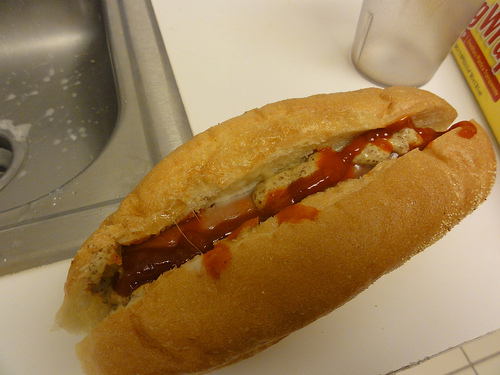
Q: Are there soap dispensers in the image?
A: No, there are no soap dispensers.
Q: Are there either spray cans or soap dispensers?
A: No, there are no soap dispensers or spray cans.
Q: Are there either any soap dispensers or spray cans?
A: No, there are no soap dispensers or spray cans.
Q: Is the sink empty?
A: Yes, the sink is empty.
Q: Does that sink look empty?
A: Yes, the sink is empty.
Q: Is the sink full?
A: No, the sink is empty.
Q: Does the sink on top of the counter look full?
A: No, the sink is empty.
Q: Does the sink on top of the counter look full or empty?
A: The sink is empty.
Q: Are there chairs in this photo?
A: No, there are no chairs.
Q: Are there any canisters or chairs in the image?
A: No, there are no chairs or canisters.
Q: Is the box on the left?
A: No, the box is on the right of the image.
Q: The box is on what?
A: The box is on the counter.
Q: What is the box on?
A: The box is on the counter.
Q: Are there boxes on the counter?
A: Yes, there is a box on the counter.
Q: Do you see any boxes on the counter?
A: Yes, there is a box on the counter.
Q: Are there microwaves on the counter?
A: No, there is a box on the counter.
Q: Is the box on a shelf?
A: No, the box is on a counter.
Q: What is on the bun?
A: The seeds are on the bun.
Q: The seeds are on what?
A: The seeds are on the bun.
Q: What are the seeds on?
A: The seeds are on the bun.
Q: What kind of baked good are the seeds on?
A: The seeds are on the bun.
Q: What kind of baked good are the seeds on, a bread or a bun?
A: The seeds are on a bun.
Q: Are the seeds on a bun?
A: Yes, the seeds are on a bun.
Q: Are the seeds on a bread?
A: No, the seeds are on a bun.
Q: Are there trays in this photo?
A: No, there are no trays.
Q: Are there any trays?
A: No, there are no trays.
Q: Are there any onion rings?
A: No, there are no onion rings.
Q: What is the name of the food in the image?
A: The food is a bun.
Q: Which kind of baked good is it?
A: The food is a bun.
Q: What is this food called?
A: This is a bun.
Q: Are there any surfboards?
A: No, there are no surfboards.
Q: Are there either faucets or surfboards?
A: No, there are no surfboards or faucets.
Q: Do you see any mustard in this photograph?
A: Yes, there is mustard.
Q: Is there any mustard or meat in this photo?
A: Yes, there is mustard.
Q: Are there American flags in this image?
A: No, there are no American flags.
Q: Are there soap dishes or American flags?
A: No, there are no American flags or soap dishes.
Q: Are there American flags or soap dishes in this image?
A: No, there are no American flags or soap dishes.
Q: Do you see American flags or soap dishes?
A: No, there are no American flags or soap dishes.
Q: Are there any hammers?
A: No, there are no hammers.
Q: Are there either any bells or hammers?
A: No, there are no hammers or bells.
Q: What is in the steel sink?
A: The drain is in the sink.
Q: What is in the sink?
A: The drain is in the sink.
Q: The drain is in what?
A: The drain is in the sink.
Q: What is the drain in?
A: The drain is in the sink.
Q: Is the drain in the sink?
A: Yes, the drain is in the sink.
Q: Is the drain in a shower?
A: No, the drain is in the sink.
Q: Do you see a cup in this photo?
A: Yes, there is a cup.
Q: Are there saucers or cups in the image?
A: Yes, there is a cup.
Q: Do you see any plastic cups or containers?
A: Yes, there is a plastic cup.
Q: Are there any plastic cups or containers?
A: Yes, there is a plastic cup.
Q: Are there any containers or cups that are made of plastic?
A: Yes, the cup is made of plastic.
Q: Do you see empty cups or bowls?
A: Yes, there is an empty cup.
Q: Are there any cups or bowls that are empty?
A: Yes, the cup is empty.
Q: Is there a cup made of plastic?
A: Yes, there is a cup that is made of plastic.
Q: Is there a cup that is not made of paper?
A: Yes, there is a cup that is made of plastic.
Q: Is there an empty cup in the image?
A: Yes, there is an empty cup.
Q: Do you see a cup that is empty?
A: Yes, there is a cup that is empty.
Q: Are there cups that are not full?
A: Yes, there is a empty cup.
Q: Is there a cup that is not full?
A: Yes, there is a empty cup.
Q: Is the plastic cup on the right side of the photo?
A: Yes, the cup is on the right of the image.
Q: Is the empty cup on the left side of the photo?
A: No, the cup is on the right of the image.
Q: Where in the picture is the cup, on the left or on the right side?
A: The cup is on the right of the image.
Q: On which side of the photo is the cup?
A: The cup is on the right of the image.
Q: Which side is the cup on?
A: The cup is on the right of the image.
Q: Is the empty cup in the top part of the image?
A: Yes, the cup is in the top of the image.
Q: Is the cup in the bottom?
A: No, the cup is in the top of the image.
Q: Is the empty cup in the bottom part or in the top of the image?
A: The cup is in the top of the image.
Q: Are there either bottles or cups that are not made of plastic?
A: No, there is a cup but it is made of plastic.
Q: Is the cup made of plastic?
A: Yes, the cup is made of plastic.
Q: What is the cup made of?
A: The cup is made of plastic.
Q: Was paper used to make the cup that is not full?
A: No, the cup is made of plastic.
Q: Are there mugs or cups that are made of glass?
A: No, there is a cup but it is made of plastic.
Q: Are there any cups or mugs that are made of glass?
A: No, there is a cup but it is made of plastic.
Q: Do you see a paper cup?
A: No, there is a cup but it is made of plastic.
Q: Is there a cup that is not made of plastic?
A: No, there is a cup but it is made of plastic.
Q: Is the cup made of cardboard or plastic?
A: The cup is made of plastic.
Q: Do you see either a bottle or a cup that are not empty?
A: No, there is a cup but it is empty.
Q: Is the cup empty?
A: Yes, the cup is empty.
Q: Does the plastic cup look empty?
A: Yes, the cup is empty.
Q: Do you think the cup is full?
A: No, the cup is empty.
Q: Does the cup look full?
A: No, the cup is empty.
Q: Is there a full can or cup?
A: No, there is a cup but it is empty.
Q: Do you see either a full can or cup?
A: No, there is a cup but it is empty.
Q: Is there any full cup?
A: No, there is a cup but it is empty.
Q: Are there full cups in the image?
A: No, there is a cup but it is empty.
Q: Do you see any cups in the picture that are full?
A: No, there is a cup but it is empty.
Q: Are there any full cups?
A: No, there is a cup but it is empty.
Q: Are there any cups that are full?
A: No, there is a cup but it is empty.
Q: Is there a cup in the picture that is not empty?
A: No, there is a cup but it is empty.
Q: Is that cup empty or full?
A: The cup is empty.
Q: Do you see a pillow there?
A: No, there are no pillows.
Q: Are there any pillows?
A: No, there are no pillows.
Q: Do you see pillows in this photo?
A: No, there are no pillows.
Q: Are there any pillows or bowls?
A: No, there are no pillows or bowls.